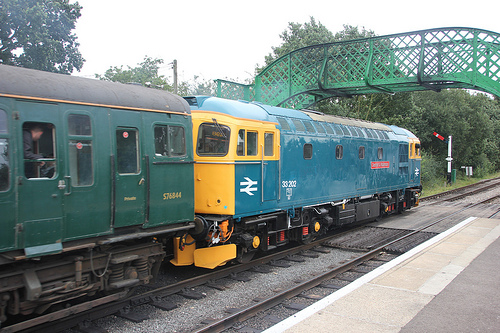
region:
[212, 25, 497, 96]
Green overpass above railroad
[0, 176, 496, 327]
Railroad track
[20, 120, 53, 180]
Person in window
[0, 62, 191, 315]
Green train car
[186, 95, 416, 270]
Blue and yellow train car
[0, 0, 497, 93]
Bright sky with no clouds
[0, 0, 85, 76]
Tree with green leaves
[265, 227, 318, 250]
Red shocks under train car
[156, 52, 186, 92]
Wooden utility pole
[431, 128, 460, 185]
Railroad signal with red and white bands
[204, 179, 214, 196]
yellow paint on train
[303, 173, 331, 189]
green paint on train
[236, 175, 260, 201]
white sign on train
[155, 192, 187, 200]
yellow numbers on train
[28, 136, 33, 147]
man wearing grey shirt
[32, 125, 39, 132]
man has is black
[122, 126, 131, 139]
red sticker in window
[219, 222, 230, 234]
orange paint on train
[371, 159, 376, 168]
red lablel on train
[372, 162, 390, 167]
grey lettering on label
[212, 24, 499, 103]
tall green metal bridge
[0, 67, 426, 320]
a train car and a half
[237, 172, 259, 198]
white writing on train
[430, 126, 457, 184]
switch signal for train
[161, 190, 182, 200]
yellow writing on train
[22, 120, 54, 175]
rail way employee working on train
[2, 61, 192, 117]
black roof of train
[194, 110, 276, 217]
yellow front of train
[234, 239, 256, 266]
front of train wheel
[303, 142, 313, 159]
small window in train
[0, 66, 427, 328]
Train moving forward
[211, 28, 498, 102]
Bridge across the train tracks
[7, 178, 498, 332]
Train tracks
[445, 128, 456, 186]
Pole in front of the train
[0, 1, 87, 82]
Tree on the side of the train tracks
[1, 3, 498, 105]
Clear sky outside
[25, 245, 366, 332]
Gravel between the train tracks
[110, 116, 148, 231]
Green door on the train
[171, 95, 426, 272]
Front of the train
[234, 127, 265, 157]
windows on the train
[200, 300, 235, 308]
the small rocks on the tracks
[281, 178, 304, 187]
numbers on the train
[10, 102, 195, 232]
the train is green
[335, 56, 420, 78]
the overpass is green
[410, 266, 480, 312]
the street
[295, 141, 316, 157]
window on the train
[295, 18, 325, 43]
a tall bush